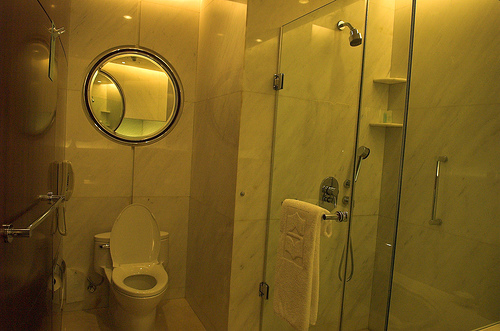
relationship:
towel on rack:
[274, 199, 334, 330] [281, 197, 347, 222]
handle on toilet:
[99, 243, 110, 251] [94, 202, 172, 330]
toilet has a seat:
[94, 202, 172, 330] [111, 262, 169, 297]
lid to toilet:
[109, 205, 161, 266] [94, 202, 172, 330]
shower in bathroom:
[259, 0, 499, 331] [2, 1, 498, 328]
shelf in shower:
[371, 76, 407, 87] [259, 0, 499, 331]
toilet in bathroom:
[94, 202, 172, 330] [2, 1, 498, 328]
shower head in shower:
[338, 19, 362, 45] [259, 0, 499, 331]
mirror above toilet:
[87, 51, 180, 141] [94, 202, 172, 330]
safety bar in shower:
[429, 156, 448, 226] [259, 0, 499, 331]